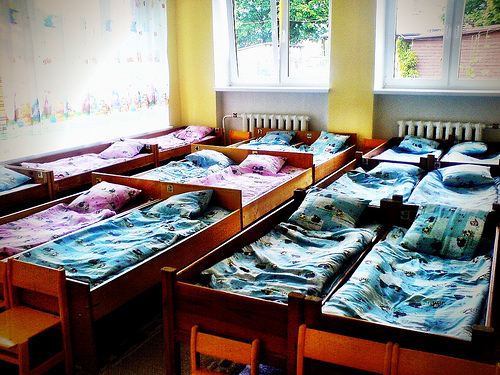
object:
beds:
[294, 188, 500, 375]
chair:
[1, 256, 75, 375]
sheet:
[15, 206, 232, 288]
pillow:
[66, 180, 142, 215]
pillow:
[235, 153, 289, 175]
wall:
[400, 30, 498, 84]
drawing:
[13, 98, 41, 129]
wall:
[1, 1, 179, 163]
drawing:
[43, 14, 58, 28]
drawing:
[142, 88, 161, 109]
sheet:
[200, 219, 383, 305]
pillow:
[175, 124, 215, 143]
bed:
[123, 124, 224, 165]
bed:
[1, 180, 241, 375]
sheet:
[0, 201, 117, 258]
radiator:
[222, 111, 312, 143]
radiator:
[394, 118, 496, 144]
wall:
[165, 0, 231, 139]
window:
[221, 0, 329, 90]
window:
[382, 0, 499, 94]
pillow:
[144, 189, 215, 219]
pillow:
[287, 186, 373, 232]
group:
[0, 122, 498, 375]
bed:
[191, 127, 299, 159]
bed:
[354, 132, 456, 167]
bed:
[431, 136, 500, 171]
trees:
[234, 0, 279, 50]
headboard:
[160, 182, 242, 217]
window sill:
[217, 83, 331, 97]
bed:
[159, 188, 393, 375]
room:
[1, 0, 500, 375]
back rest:
[0, 258, 68, 317]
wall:
[372, 87, 498, 155]